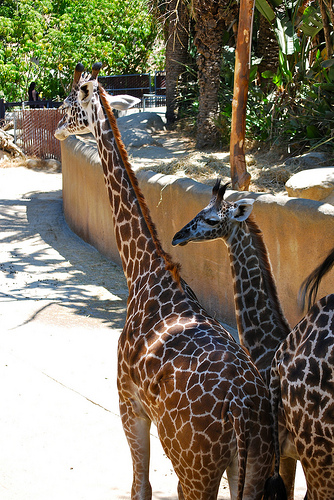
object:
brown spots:
[314, 327, 333, 369]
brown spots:
[240, 310, 271, 341]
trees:
[135, 2, 151, 47]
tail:
[262, 360, 289, 500]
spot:
[304, 356, 320, 388]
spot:
[312, 327, 333, 359]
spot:
[304, 384, 331, 423]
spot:
[289, 380, 307, 409]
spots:
[215, 385, 235, 411]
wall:
[62, 143, 76, 223]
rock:
[285, 168, 334, 202]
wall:
[201, 254, 226, 317]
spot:
[256, 290, 269, 311]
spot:
[243, 287, 259, 309]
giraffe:
[171, 177, 334, 500]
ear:
[232, 198, 252, 221]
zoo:
[0, 0, 330, 500]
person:
[28, 82, 40, 109]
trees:
[3, 1, 19, 99]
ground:
[4, 167, 44, 221]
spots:
[124, 341, 133, 365]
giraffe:
[53, 62, 273, 500]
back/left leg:
[176, 462, 223, 500]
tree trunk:
[165, 0, 189, 131]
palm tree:
[192, 0, 239, 150]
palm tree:
[252, 0, 279, 96]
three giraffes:
[53, 61, 334, 500]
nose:
[173, 230, 184, 241]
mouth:
[177, 237, 189, 247]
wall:
[95, 230, 108, 245]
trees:
[60, 0, 74, 29]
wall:
[283, 257, 301, 304]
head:
[54, 62, 103, 142]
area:
[54, 86, 75, 114]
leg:
[225, 442, 274, 499]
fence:
[15, 108, 68, 159]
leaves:
[20, 13, 29, 27]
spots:
[234, 350, 247, 362]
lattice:
[33, 114, 35, 146]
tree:
[229, 0, 256, 191]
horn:
[91, 62, 102, 79]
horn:
[73, 62, 85, 86]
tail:
[228, 399, 250, 500]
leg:
[118, 377, 152, 500]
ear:
[110, 95, 142, 111]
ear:
[78, 81, 93, 108]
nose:
[53, 126, 58, 134]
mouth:
[54, 124, 66, 141]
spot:
[143, 296, 161, 317]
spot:
[147, 340, 165, 358]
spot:
[183, 327, 201, 339]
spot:
[172, 353, 191, 371]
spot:
[156, 360, 175, 401]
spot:
[260, 333, 279, 351]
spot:
[254, 348, 275, 373]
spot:
[259, 320, 277, 334]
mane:
[245, 212, 292, 338]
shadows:
[0, 188, 131, 332]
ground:
[1, 414, 118, 498]